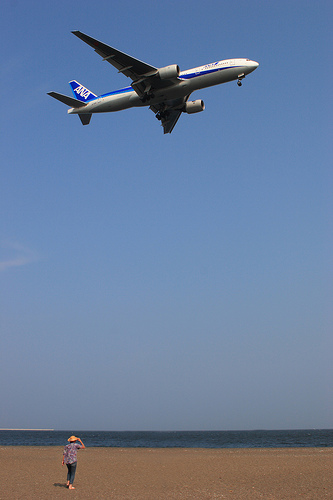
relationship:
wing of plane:
[69, 28, 177, 87] [39, 18, 264, 140]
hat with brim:
[66, 434, 80, 443] [66, 437, 77, 441]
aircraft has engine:
[46, 29, 259, 134] [146, 63, 179, 82]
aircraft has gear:
[46, 29, 259, 134] [140, 96, 174, 127]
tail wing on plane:
[58, 78, 104, 135] [47, 23, 279, 154]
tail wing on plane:
[79, 111, 92, 128] [35, 22, 248, 146]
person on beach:
[59, 432, 86, 490] [2, 445, 332, 497]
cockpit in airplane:
[246, 58, 254, 65] [38, 28, 264, 136]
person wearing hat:
[62, 435, 86, 489] [67, 432, 80, 444]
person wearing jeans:
[62, 435, 86, 489] [64, 461, 75, 489]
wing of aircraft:
[153, 91, 191, 134] [46, 29, 259, 134]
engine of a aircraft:
[176, 98, 208, 112] [46, 29, 259, 134]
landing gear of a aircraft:
[234, 72, 247, 87] [46, 29, 259, 134]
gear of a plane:
[138, 84, 161, 113] [39, 18, 264, 140]